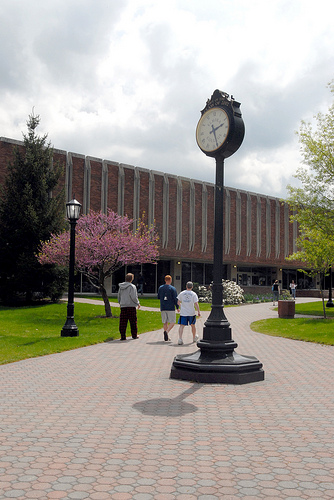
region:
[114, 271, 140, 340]
person is walking next to person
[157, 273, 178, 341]
person is walking next to person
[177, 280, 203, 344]
person is walking next to person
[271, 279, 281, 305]
person is walking in front of person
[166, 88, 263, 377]
large clock tower in front of building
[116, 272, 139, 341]
person wearing gray hoodie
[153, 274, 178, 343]
person with red hair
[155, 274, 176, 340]
person wearing gray shorts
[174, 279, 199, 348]
person wearing white t-shirt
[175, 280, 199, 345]
person wearing white sneakers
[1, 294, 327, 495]
pale red and blue pavers covering walkways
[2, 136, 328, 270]
wide brick wall with vertical strips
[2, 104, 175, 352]
lamppost and trees on green grass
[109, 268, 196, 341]
three people strolling on sidewalk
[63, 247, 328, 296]
large dark windows on street level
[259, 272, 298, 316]
women in back of large receptacle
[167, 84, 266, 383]
clock over black pole and foundation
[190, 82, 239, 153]
curved ornamentation on clock frame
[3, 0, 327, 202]
clouds covering blue-gray sky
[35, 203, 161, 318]
small slanted tree with pink blossums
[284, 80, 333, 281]
part of a large green tree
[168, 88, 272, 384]
a tall black clock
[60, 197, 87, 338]
a tall black lamp pole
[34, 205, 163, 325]
a large purple tree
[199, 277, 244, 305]
a large white tree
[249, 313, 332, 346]
a section of green grass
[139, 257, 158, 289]
a window of a building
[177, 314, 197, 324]
a man's black and blue shorts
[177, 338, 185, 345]
a white tennis shoe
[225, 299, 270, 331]
part of a walkway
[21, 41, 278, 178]
a cloudy sky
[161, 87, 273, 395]
an outside black clock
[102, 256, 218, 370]
three boys walking to building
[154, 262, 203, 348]
a red headed boy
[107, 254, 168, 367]
guy in grey jacket and black pants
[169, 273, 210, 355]
boy in white shirt and blue shorts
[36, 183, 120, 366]
a street light in grass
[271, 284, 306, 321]
a octogonal trash can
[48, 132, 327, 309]
a college building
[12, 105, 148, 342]
trees on a college campus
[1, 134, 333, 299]
the building is big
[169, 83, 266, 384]
the clock is black and white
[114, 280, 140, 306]
the sweatshirt is gray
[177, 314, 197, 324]
the shorts are black and blue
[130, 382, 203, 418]
a shadow of the clock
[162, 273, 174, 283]
the boy has red hair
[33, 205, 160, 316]
the tree is pink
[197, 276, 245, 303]
the bush is white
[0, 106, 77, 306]
the tree is dark and tall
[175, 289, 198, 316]
the shirt is white